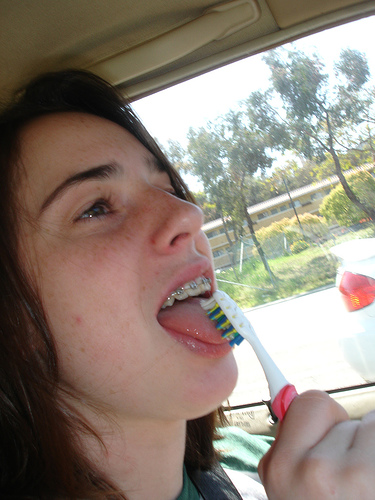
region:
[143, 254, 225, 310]
these are teeth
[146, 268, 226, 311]
the teeth have braces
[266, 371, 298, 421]
the pink grip of a toothbrush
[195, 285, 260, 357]
the head of a toothbrush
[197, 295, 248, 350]
the bristles of a toothbrush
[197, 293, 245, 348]
the bristles are on her tongue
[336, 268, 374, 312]
this is a tail light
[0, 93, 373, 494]
she is holding the toothbrush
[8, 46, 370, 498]
she is holding the toothbrush to her tongue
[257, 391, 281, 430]
this is a lock on a door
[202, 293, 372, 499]
A toothbrush in the woman's hand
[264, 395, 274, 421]
A lock on the door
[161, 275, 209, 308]
The woman has braces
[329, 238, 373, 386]
A car outside the window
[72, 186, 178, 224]
The eyes of the woman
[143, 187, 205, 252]
The nose of the woman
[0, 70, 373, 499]
A woman sitting in a car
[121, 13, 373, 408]
A window in the car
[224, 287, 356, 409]
A street outside the window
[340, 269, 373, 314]
A tail light on the car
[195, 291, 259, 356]
tooth brush on a toung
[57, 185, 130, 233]
girls eye and long eye lashes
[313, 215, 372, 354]
car tail light and white fin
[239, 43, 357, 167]
large tall tree and sky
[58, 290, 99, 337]
pimple on side of face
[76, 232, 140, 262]
freckles on side of face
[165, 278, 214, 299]
silver braces on large teeth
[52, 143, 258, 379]
girl brushing her tong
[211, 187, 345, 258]
large yellow building with many windows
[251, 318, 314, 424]
pink rubber grip with finger on top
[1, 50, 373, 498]
girl brushing her tongue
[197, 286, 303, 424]
pink toothbrush on tongue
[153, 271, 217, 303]
metal braces on teeth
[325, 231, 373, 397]
white car rear with red stop lights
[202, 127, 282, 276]
tree in ground with green leafs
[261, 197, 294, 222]
several windows of building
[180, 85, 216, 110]
bright clear sky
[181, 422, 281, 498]
green shirt of gril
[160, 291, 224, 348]
tongue of girl with brush on it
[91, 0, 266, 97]
assistant handle on car